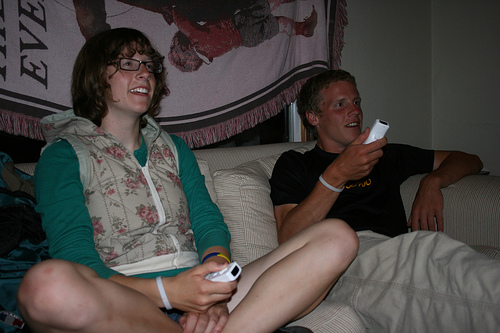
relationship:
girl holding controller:
[224, 33, 316, 331] [360, 118, 395, 151]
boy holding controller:
[269, 64, 499, 333] [360, 118, 395, 151]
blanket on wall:
[3, 2, 328, 40] [21, 0, 428, 59]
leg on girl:
[223, 216, 360, 331] [7, 26, 359, 331]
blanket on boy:
[350, 225, 499, 331] [267, 69, 482, 256]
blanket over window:
[3, 2, 352, 150] [227, 103, 298, 143]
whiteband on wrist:
[318, 168, 347, 201] [322, 161, 352, 200]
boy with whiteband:
[277, 84, 472, 298] [318, 168, 347, 201]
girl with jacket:
[7, 26, 359, 331] [36, 104, 229, 269]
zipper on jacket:
[138, 165, 167, 227] [36, 104, 229, 269]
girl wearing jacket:
[7, 26, 359, 331] [36, 104, 229, 269]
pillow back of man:
[218, 163, 274, 254] [293, 58, 470, 308]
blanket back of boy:
[324, 225, 499, 332] [269, 64, 499, 333]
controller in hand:
[360, 117, 397, 157] [323, 124, 393, 191]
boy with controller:
[269, 64, 499, 333] [360, 117, 397, 157]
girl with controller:
[7, 26, 359, 331] [194, 260, 244, 283]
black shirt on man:
[268, 140, 438, 240] [272, 56, 459, 274]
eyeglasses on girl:
[93, 51, 163, 73] [7, 26, 359, 331]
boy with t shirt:
[269, 64, 499, 333] [265, 140, 440, 243]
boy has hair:
[269, 64, 499, 333] [52, 22, 145, 123]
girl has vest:
[7, 26, 359, 331] [42, 107, 198, 267]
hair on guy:
[295, 67, 357, 135] [271, 67, 497, 330]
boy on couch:
[269, 64, 499, 333] [43, 87, 499, 329]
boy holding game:
[269, 64, 499, 333] [366, 120, 391, 145]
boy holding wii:
[269, 64, 499, 333] [364, 113, 391, 145]